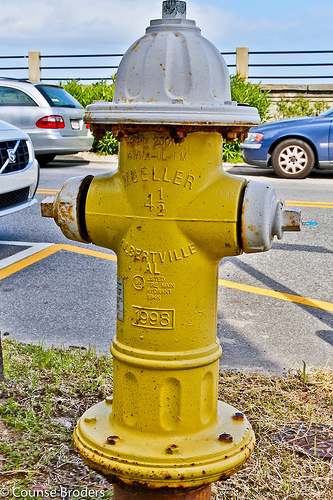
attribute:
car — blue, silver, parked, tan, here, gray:
[271, 123, 331, 172]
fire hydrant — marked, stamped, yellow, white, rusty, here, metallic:
[51, 42, 276, 418]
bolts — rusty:
[94, 382, 236, 469]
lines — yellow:
[222, 274, 315, 317]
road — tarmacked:
[226, 302, 296, 328]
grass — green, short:
[113, 151, 116, 152]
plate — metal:
[170, 477, 197, 495]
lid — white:
[129, 47, 197, 65]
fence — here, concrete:
[230, 43, 329, 93]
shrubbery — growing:
[250, 95, 310, 119]